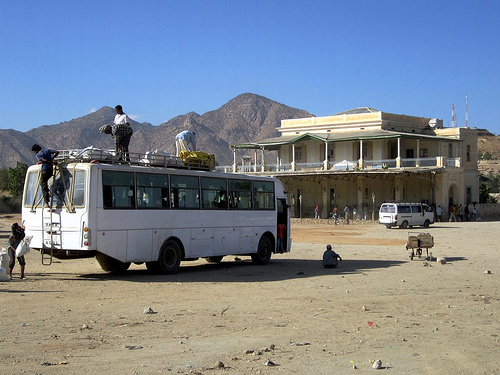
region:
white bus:
[19, 139, 316, 276]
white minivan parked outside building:
[372, 193, 453, 233]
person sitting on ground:
[318, 241, 351, 273]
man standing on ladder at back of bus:
[24, 135, 87, 228]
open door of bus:
[270, 190, 298, 257]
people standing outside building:
[304, 199, 379, 234]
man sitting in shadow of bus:
[298, 233, 355, 270]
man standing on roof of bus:
[96, 96, 205, 180]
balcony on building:
[230, 132, 450, 177]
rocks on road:
[172, 338, 347, 368]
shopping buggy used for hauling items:
[377, 221, 445, 276]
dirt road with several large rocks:
[36, 275, 466, 361]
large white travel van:
[0, 130, 331, 302]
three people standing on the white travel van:
[31, 115, 231, 210]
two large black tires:
[141, 237, 287, 279]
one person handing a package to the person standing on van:
[6, 220, 66, 372]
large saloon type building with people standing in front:
[245, 125, 475, 237]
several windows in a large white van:
[85, 171, 285, 219]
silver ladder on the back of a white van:
[32, 167, 82, 288]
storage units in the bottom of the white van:
[87, 228, 297, 283]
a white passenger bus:
[9, 98, 298, 264]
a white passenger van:
[371, 199, 434, 229]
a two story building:
[218, 97, 472, 224]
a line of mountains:
[0, 81, 312, 198]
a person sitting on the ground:
[318, 239, 347, 277]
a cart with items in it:
[396, 225, 436, 268]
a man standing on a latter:
[21, 136, 73, 225]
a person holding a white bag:
[6, 212, 41, 300]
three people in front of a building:
[293, 188, 363, 230]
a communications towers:
[441, 79, 477, 143]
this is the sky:
[115, 23, 258, 66]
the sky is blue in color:
[93, 20, 343, 42]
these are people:
[81, 103, 202, 154]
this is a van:
[369, 200, 437, 223]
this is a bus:
[19, 163, 299, 255]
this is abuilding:
[283, 114, 464, 207]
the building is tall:
[276, 114, 464, 203]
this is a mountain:
[151, 100, 291, 148]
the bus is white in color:
[27, 170, 289, 255]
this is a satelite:
[446, 102, 471, 126]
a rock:
[363, 351, 390, 372]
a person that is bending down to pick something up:
[167, 117, 207, 174]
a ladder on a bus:
[33, 130, 63, 272]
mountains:
[3, 73, 490, 202]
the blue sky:
[0, 4, 498, 136]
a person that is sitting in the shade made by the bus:
[322, 237, 342, 269]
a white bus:
[23, 148, 320, 267]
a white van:
[376, 194, 446, 227]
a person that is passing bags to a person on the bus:
[11, 212, 27, 289]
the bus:
[0, 130, 330, 291]